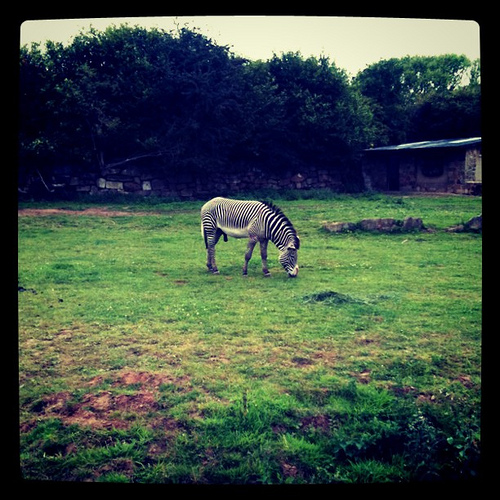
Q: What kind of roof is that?
A: An old blue roof.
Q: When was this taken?
A: During the day time.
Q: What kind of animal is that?
A: A large zebra.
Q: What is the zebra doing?
A: Eating grass.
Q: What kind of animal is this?
A: A zebra.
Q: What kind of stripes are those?
A: Black and white stripes.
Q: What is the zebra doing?
A: Eating grass.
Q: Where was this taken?
A: A large patch of grass.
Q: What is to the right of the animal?
A: A building.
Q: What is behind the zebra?
A: A brice wall.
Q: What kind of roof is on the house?
A: A blue roof.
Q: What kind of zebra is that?
A: A male zebra.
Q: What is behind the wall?
A: Green trees.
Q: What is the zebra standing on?
A: Grass.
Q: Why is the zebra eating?
A: He is hungry.